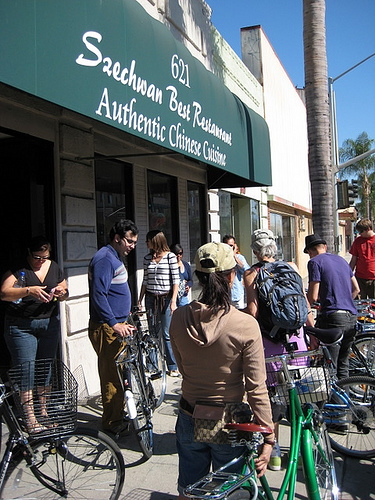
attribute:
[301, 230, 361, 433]
man — black 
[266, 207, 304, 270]
window — large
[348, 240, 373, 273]
shirt — red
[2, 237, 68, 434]
she — looking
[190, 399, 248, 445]
bag — Gucci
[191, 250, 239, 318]
hair — dark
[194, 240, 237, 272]
cap — beige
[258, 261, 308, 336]
backpack — light blue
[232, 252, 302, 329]
blue backpack — large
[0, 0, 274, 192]
awning — green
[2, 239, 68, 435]
woman — large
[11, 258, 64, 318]
tee shirt — black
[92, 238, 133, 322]
shirt — blue 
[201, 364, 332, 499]
bike — light green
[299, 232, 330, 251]
hat — black 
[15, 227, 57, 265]
hair — dark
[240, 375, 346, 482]
bike — green 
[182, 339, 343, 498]
bike — green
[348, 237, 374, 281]
shirt — red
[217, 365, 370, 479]
bicycle — silver 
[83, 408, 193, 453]
shadow — black 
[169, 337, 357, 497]
bike — green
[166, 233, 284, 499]
woman — dark haired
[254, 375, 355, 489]
bicycle — black, white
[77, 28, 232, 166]
letters — White 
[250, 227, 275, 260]
hair — gray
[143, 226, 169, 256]
hair — long, brown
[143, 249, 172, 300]
shirt — striped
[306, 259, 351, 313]
shirt — purple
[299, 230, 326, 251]
hat — black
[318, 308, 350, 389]
jeans — black